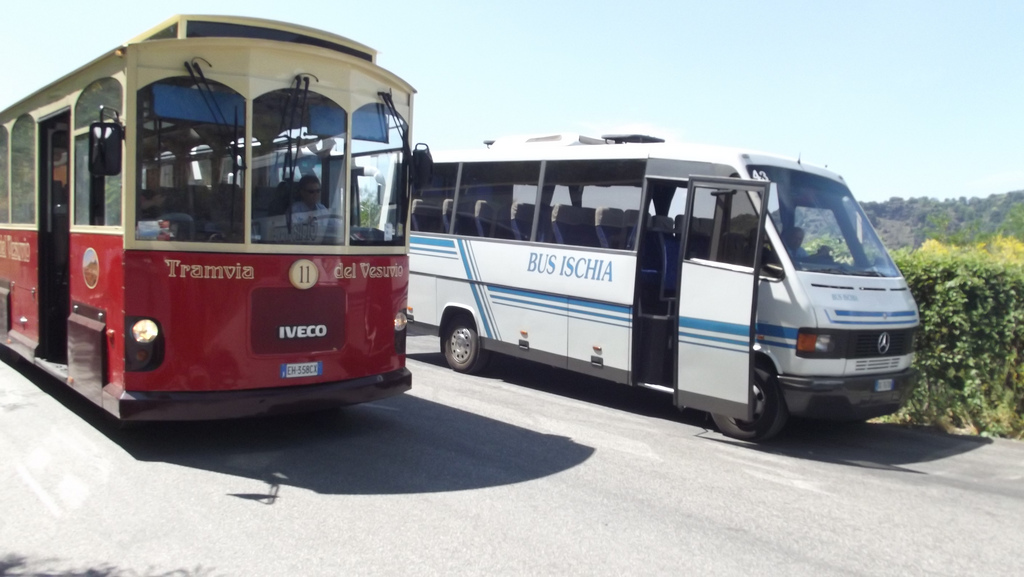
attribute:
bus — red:
[2, 14, 436, 423]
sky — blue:
[2, 7, 1021, 207]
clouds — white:
[3, 3, 1019, 204]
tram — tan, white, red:
[0, 14, 434, 423]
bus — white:
[455, 114, 788, 410]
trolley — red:
[7, 67, 366, 441]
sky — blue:
[600, 48, 856, 135]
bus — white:
[431, 110, 900, 424]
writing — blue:
[502, 229, 626, 284]